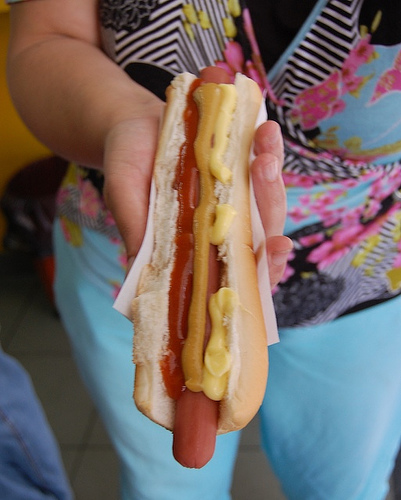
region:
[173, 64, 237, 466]
hot dog in bun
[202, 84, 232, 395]
melted cheese on bun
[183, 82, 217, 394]
mustard line on hot dog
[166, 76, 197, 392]
ketchup line on hot dog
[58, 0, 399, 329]
floral cotton womans shirt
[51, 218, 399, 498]
blue cotton dress pants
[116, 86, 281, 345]
white paper napkin in hand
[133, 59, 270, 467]
hot dog in napkin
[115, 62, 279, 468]
hot dog and napkin in hand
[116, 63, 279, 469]
dressed hot dog in hand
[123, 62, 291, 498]
long hot dog in hand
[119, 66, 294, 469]
long hot dog in bun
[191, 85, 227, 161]
mustard on top of hot dog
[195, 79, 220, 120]
yellow spicy mustard on hot dog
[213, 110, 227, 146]
dijon mustard on hot dog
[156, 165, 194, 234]
red ketchup on hot dog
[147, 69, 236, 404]
hot dog between bun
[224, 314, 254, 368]
brown and white side bun of hot dog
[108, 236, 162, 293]
white napkin below hot dog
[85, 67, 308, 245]
hand holding long hot dog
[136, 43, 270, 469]
foot long hot dog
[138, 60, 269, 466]
foot long hot dog in bun with mustard and ketchup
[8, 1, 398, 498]
woman in light blue pants and multi colored top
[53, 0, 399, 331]
woman's blouse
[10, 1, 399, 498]
woman holding hotdog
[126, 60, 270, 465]
hotdog with condiments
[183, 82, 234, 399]
mustard on footlong dog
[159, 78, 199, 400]
ketchup slathered on footlong hotdog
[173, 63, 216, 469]
footlong wiener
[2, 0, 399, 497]
woman ready to enjoy footlong hotdog slathered with mustard and ketchup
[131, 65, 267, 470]
Foot Long Hot dog in woman hand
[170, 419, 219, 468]
tip of the hot dog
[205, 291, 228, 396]
cheese on the hot dog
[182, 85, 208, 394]
mustard on the footlong hot dog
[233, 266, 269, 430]
the bread of a footlong hotdog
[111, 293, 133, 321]
part of thepper napkin holding the hotdog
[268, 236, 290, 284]
index finger holding the hot dog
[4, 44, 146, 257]
arm and hand of the person holding hot dog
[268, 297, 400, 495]
pants leg of person holding hot dog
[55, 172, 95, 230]
bottom edge of shirt of person holding hotdog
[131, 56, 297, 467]
a hot dog in a person's hand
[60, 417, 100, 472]
white stone tile of the floor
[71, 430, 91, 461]
black grout between the tiles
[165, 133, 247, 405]
hetchup and mustard on the hot dog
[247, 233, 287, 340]
white napkin under the hot dog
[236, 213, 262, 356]
tan bun of the hot dog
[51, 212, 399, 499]
a person wearing blue pants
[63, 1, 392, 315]
a person's colorful patterned shirt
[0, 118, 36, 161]
yellow wall of the room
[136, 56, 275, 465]
a foot long hot dog with ketchup and mustard